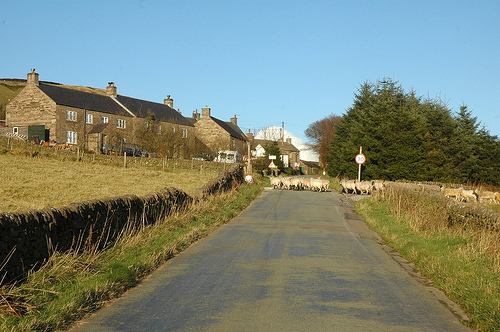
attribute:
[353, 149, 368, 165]
sign — round, red, white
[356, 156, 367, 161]
numbers — black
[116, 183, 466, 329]
road — black, dirty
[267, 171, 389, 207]
cows — crossing, white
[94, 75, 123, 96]
building — brown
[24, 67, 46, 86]
building — brick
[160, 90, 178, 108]
building — brown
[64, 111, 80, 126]
windows — white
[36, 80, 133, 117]
roof — black, sloped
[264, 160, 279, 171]
sign — triangular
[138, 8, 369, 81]
sky — blue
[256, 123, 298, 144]
something — white